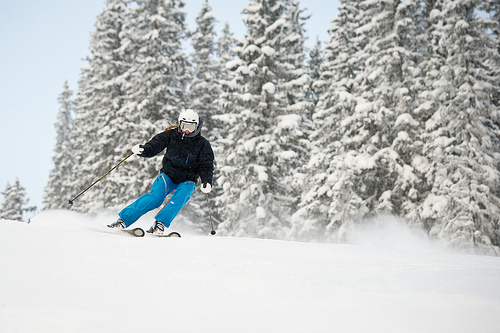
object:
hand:
[131, 144, 144, 156]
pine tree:
[41, 75, 73, 209]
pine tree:
[93, 0, 182, 216]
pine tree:
[226, 0, 311, 239]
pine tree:
[410, 0, 500, 252]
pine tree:
[348, 6, 425, 236]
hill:
[0, 206, 497, 333]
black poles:
[68, 144, 216, 236]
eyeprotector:
[178, 120, 197, 132]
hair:
[164, 123, 179, 132]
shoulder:
[163, 127, 174, 139]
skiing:
[121, 193, 189, 255]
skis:
[83, 211, 182, 238]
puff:
[31, 203, 203, 236]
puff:
[347, 211, 462, 251]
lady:
[107, 109, 215, 237]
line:
[185, 153, 197, 165]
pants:
[117, 173, 197, 229]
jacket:
[137, 127, 215, 185]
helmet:
[176, 109, 201, 129]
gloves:
[200, 182, 213, 193]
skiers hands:
[200, 182, 212, 194]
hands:
[199, 182, 213, 194]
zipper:
[160, 175, 167, 196]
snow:
[0, 0, 500, 236]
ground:
[0, 210, 500, 331]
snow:
[0, 207, 495, 330]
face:
[179, 119, 197, 135]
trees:
[44, 0, 499, 252]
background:
[0, 0, 500, 267]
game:
[0, 83, 500, 333]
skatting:
[94, 110, 249, 252]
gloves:
[131, 144, 144, 156]